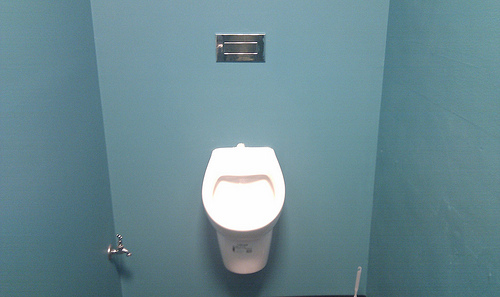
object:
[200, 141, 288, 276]
urinal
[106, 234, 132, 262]
spigot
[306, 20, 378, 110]
wall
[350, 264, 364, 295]
handle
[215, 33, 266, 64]
box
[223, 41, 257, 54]
shape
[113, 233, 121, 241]
knob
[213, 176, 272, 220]
bowl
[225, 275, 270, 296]
shadow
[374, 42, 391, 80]
corner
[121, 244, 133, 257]
spout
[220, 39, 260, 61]
square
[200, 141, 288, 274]
toilet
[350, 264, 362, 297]
brush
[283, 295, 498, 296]
floor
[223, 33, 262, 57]
mount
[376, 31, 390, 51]
trim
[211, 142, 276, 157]
tank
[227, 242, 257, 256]
logo